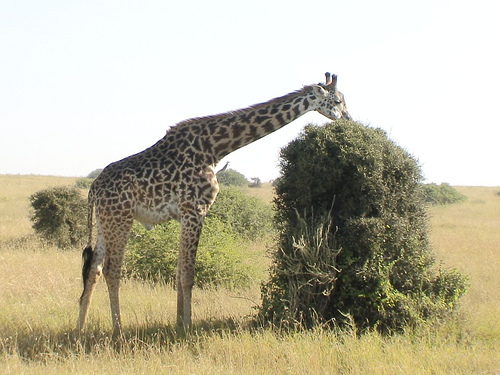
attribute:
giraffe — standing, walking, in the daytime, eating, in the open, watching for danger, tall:
[76, 72, 351, 344]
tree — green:
[279, 109, 466, 334]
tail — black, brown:
[76, 189, 103, 302]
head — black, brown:
[295, 67, 358, 130]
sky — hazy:
[65, 0, 487, 66]